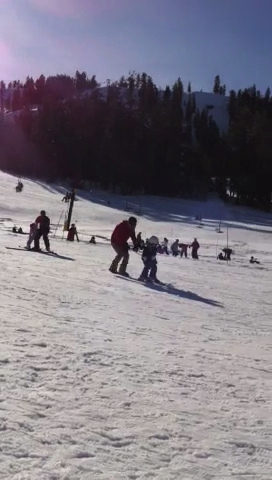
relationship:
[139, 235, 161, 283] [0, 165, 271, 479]
child skiing on hill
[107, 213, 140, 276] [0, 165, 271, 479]
adult skiing on hill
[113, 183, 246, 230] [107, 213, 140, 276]
shadow of adult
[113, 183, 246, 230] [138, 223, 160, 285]
shadow of child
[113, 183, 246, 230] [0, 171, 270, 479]
shadow on surface of snow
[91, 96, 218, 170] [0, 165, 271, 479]
trees bordering hill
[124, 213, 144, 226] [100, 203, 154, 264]
hat on person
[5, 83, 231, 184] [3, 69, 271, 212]
rock formation between trees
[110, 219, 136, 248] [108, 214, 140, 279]
jacket on person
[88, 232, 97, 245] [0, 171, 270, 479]
object on snow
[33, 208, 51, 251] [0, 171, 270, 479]
man in snow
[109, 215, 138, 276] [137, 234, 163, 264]
adult near child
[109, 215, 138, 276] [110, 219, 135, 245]
adult wearing jacket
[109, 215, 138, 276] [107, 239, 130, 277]
adult wearing brown pants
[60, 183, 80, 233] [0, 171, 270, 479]
pole in snow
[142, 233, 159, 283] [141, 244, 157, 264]
child wearing coat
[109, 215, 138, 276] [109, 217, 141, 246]
adult in red coat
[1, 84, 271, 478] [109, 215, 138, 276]
hillside with adult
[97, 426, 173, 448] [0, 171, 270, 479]
footprints in snow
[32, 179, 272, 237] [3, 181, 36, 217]
shadow cast ground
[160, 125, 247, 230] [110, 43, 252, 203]
lights on building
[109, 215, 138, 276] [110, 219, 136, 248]
adult in jacket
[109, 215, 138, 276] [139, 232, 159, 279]
adult teaches child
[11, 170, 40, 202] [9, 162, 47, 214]
people ride chairlift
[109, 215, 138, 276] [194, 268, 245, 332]
adult sitting in snow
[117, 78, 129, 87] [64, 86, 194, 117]
chimney on roof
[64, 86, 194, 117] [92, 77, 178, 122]
roof behind tree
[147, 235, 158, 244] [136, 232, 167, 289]
hat on a child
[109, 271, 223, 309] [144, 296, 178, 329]
shadows cast in snow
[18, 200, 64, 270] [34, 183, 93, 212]
man on hillside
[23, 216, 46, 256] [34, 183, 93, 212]
child on hillside